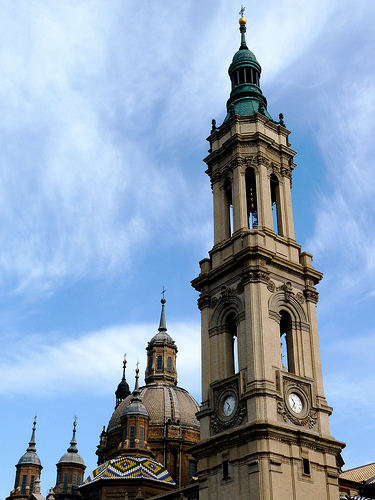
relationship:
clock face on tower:
[282, 388, 311, 422] [190, 4, 347, 498]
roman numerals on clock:
[286, 393, 303, 413] [288, 391, 302, 412]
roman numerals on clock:
[286, 393, 303, 413] [223, 394, 235, 415]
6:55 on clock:
[282, 387, 309, 419] [288, 392, 304, 413]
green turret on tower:
[220, 46, 272, 94] [190, 4, 347, 498]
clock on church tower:
[288, 390, 304, 411] [186, 2, 345, 498]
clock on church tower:
[223, 395, 236, 416] [186, 2, 345, 498]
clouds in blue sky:
[1, 0, 374, 497] [3, 7, 365, 378]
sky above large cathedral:
[3, 4, 366, 270] [179, 4, 364, 500]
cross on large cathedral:
[231, 2, 254, 21] [179, 4, 364, 500]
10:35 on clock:
[280, 387, 312, 432] [286, 389, 303, 411]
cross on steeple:
[160, 285, 168, 299] [108, 283, 202, 491]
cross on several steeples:
[73, 413, 78, 422] [6, 287, 196, 495]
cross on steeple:
[33, 411, 37, 419] [6, 411, 44, 498]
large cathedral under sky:
[179, 4, 363, 492] [0, 0, 374, 498]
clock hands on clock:
[290, 395, 300, 409] [287, 390, 314, 413]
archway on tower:
[239, 152, 266, 234] [201, 232, 314, 394]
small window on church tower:
[292, 447, 326, 478] [186, 2, 345, 498]